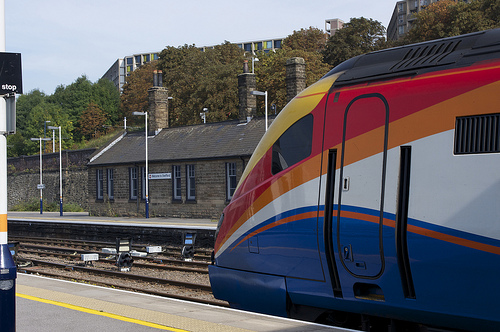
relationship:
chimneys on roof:
[145, 59, 307, 131] [100, 124, 271, 175]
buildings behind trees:
[91, 1, 454, 71] [83, 34, 298, 117]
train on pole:
[230, 54, 490, 328] [3, 51, 26, 331]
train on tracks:
[230, 54, 490, 328] [24, 209, 207, 307]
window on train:
[262, 113, 322, 182] [230, 54, 490, 328]